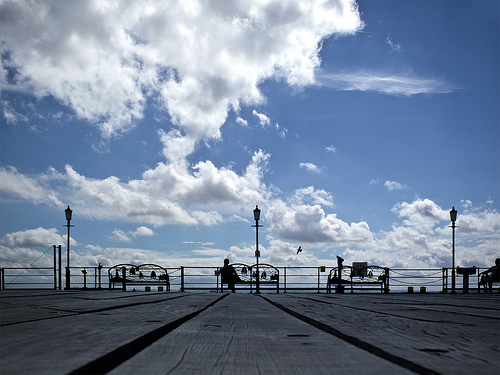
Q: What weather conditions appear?
A: It is clear.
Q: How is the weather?
A: It is clear.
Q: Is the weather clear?
A: Yes, it is clear.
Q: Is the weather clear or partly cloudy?
A: It is clear.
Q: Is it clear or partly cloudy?
A: It is clear.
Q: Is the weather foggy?
A: No, it is clear.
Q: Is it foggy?
A: No, it is clear.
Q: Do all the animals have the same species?
A: Yes, all the animals are birds.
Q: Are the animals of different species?
A: No, all the animals are birds.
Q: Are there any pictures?
A: No, there are no pictures.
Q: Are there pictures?
A: No, there are no pictures.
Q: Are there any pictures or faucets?
A: No, there are no pictures or faucets.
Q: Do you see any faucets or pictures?
A: No, there are no pictures or faucets.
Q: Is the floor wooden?
A: Yes, the floor is wooden.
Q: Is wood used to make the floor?
A: Yes, the floor is made of wood.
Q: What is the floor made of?
A: The floor is made of wood.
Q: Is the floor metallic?
A: No, the floor is wooden.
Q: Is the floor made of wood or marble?
A: The floor is made of wood.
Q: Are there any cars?
A: No, there are no cars.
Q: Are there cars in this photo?
A: No, there are no cars.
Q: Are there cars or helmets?
A: No, there are no cars or helmets.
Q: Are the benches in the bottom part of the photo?
A: Yes, the benches are in the bottom of the image.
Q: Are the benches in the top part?
A: No, the benches are in the bottom of the image.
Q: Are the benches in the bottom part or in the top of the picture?
A: The benches are in the bottom of the image.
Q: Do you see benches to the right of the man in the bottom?
A: Yes, there are benches to the right of the man.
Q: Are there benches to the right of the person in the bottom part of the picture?
A: Yes, there are benches to the right of the man.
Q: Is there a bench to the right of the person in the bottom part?
A: Yes, there are benches to the right of the man.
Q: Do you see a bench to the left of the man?
A: No, the benches are to the right of the man.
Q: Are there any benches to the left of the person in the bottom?
A: No, the benches are to the right of the man.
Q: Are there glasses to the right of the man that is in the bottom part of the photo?
A: No, there are benches to the right of the man.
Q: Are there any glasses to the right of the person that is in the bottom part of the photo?
A: No, there are benches to the right of the man.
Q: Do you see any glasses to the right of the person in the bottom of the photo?
A: No, there are benches to the right of the man.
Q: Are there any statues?
A: No, there are no statues.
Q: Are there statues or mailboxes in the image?
A: No, there are no statues or mailboxes.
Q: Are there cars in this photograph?
A: No, there are no cars.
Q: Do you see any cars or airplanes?
A: No, there are no cars or airplanes.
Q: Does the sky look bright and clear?
A: Yes, the sky is bright and clear.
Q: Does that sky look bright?
A: Yes, the sky is bright.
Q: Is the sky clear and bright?
A: Yes, the sky is clear and bright.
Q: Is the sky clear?
A: Yes, the sky is clear.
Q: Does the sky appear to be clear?
A: Yes, the sky is clear.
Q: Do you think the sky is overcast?
A: No, the sky is clear.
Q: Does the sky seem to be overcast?
A: No, the sky is clear.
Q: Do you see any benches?
A: Yes, there is a bench.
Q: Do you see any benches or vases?
A: Yes, there is a bench.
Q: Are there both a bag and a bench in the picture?
A: No, there is a bench but no bags.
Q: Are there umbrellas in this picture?
A: No, there are no umbrellas.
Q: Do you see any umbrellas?
A: No, there are no umbrellas.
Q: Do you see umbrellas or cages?
A: No, there are no umbrellas or cages.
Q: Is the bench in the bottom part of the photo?
A: Yes, the bench is in the bottom of the image.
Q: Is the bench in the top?
A: No, the bench is in the bottom of the image.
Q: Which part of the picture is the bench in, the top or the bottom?
A: The bench is in the bottom of the image.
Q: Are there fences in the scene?
A: Yes, there is a fence.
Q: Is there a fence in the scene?
A: Yes, there is a fence.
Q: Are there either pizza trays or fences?
A: Yes, there is a fence.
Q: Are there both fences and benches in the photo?
A: Yes, there are both a fence and a bench.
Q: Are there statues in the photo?
A: No, there are no statues.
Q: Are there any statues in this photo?
A: No, there are no statues.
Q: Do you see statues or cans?
A: No, there are no statues or cans.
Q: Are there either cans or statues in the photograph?
A: No, there are no statues or cans.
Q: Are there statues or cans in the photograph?
A: No, there are no statues or cans.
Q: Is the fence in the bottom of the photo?
A: Yes, the fence is in the bottom of the image.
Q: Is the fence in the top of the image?
A: No, the fence is in the bottom of the image.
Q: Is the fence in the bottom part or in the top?
A: The fence is in the bottom of the image.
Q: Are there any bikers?
A: No, there are no bikers.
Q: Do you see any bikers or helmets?
A: No, there are no bikers or helmets.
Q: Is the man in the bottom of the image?
A: Yes, the man is in the bottom of the image.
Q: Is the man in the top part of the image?
A: No, the man is in the bottom of the image.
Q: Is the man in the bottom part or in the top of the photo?
A: The man is in the bottom of the image.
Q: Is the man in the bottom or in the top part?
A: The man is in the bottom of the image.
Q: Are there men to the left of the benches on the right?
A: Yes, there is a man to the left of the benches.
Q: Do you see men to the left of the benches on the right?
A: Yes, there is a man to the left of the benches.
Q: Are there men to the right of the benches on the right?
A: No, the man is to the left of the benches.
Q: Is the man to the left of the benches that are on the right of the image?
A: Yes, the man is to the left of the benches.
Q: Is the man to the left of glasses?
A: No, the man is to the left of the benches.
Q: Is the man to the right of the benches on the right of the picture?
A: No, the man is to the left of the benches.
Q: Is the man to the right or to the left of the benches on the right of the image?
A: The man is to the left of the benches.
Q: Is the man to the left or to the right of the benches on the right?
A: The man is to the left of the benches.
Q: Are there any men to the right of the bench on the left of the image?
A: Yes, there is a man to the right of the bench.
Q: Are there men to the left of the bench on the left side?
A: No, the man is to the right of the bench.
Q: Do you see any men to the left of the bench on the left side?
A: No, the man is to the right of the bench.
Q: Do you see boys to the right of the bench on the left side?
A: No, there is a man to the right of the bench.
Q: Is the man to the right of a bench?
A: Yes, the man is to the right of a bench.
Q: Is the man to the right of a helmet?
A: No, the man is to the right of a bench.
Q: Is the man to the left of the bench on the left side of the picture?
A: No, the man is to the right of the bench.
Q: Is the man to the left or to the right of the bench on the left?
A: The man is to the right of the bench.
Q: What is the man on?
A: The man is on the bench.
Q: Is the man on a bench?
A: Yes, the man is on a bench.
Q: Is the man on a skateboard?
A: No, the man is on a bench.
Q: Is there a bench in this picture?
A: Yes, there is a bench.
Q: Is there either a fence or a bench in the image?
A: Yes, there is a bench.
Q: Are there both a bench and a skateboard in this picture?
A: No, there is a bench but no skateboards.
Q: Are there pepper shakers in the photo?
A: No, there are no pepper shakers.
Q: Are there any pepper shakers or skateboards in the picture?
A: No, there are no pepper shakers or skateboards.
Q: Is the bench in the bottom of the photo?
A: Yes, the bench is in the bottom of the image.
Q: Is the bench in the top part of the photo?
A: No, the bench is in the bottom of the image.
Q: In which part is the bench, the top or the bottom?
A: The bench is in the bottom of the image.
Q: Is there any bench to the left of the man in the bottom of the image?
A: Yes, there is a bench to the left of the man.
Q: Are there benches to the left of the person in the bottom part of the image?
A: Yes, there is a bench to the left of the man.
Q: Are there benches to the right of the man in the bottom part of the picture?
A: No, the bench is to the left of the man.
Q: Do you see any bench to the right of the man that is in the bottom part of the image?
A: No, the bench is to the left of the man.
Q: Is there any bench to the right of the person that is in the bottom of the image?
A: No, the bench is to the left of the man.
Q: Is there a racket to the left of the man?
A: No, there is a bench to the left of the man.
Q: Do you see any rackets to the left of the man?
A: No, there is a bench to the left of the man.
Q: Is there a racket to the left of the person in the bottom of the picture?
A: No, there is a bench to the left of the man.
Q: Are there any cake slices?
A: No, there are no cake slices.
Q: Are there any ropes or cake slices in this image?
A: No, there are no cake slices or ropes.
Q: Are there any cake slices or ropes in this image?
A: No, there are no cake slices or ropes.